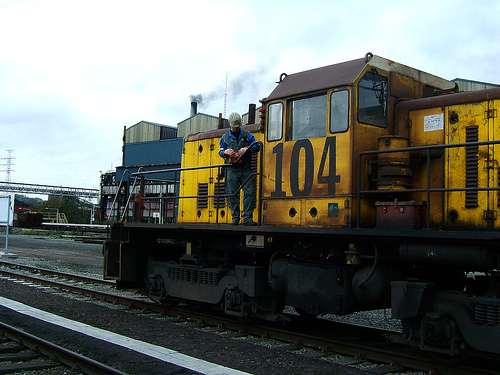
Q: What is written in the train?
A: 104.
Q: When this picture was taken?
A: During the day.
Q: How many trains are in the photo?
A: One.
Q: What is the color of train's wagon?
A: Yellow.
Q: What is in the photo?
A: A train.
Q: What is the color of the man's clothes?
A: Blue and gray.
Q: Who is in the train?
A: A man.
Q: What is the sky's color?
A: Blue.